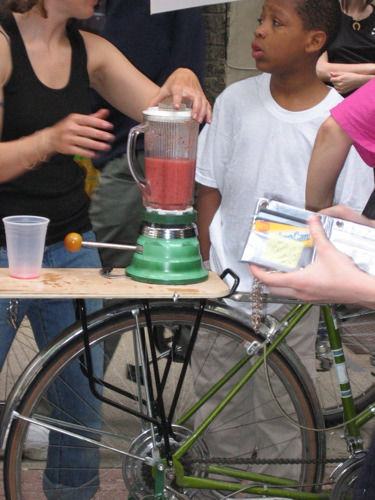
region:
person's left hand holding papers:
[247, 217, 373, 306]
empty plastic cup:
[2, 216, 49, 280]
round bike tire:
[6, 298, 328, 496]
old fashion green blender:
[121, 99, 209, 280]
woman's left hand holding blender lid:
[143, 65, 212, 125]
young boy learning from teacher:
[207, 1, 338, 495]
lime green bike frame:
[164, 293, 373, 498]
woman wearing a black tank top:
[0, 14, 92, 228]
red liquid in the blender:
[140, 154, 193, 210]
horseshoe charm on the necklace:
[352, 19, 361, 31]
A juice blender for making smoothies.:
[125, 101, 210, 284]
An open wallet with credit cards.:
[239, 198, 374, 278]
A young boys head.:
[249, 0, 340, 70]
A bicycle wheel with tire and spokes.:
[0, 299, 331, 498]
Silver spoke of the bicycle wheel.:
[211, 407, 297, 435]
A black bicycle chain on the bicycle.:
[187, 454, 356, 463]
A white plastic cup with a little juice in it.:
[4, 215, 48, 278]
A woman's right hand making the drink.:
[53, 107, 114, 161]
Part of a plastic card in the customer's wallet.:
[253, 223, 315, 243]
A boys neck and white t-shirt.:
[196, 74, 373, 270]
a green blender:
[125, 103, 209, 284]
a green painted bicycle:
[4, 295, 373, 495]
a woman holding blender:
[1, 0, 209, 496]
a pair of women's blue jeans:
[0, 225, 104, 498]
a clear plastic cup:
[3, 214, 49, 278]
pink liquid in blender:
[143, 157, 193, 208]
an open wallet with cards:
[242, 196, 372, 278]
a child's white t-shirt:
[194, 73, 373, 311]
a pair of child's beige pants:
[189, 300, 318, 497]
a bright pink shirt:
[327, 77, 373, 167]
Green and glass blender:
[118, 94, 205, 292]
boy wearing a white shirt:
[233, 106, 302, 210]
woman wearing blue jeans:
[3, 235, 117, 426]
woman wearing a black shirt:
[21, 60, 142, 226]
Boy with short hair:
[269, 7, 350, 67]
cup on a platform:
[1, 203, 66, 285]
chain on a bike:
[121, 423, 309, 484]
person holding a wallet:
[222, 172, 361, 297]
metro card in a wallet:
[249, 217, 321, 260]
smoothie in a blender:
[121, 104, 188, 205]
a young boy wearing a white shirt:
[219, 0, 340, 163]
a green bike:
[155, 307, 345, 494]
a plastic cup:
[1, 206, 54, 294]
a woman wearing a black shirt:
[7, 19, 94, 166]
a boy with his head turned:
[238, 5, 322, 77]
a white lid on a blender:
[127, 93, 217, 179]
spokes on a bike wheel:
[38, 342, 236, 469]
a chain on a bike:
[171, 446, 354, 482]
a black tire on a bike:
[2, 334, 304, 448]